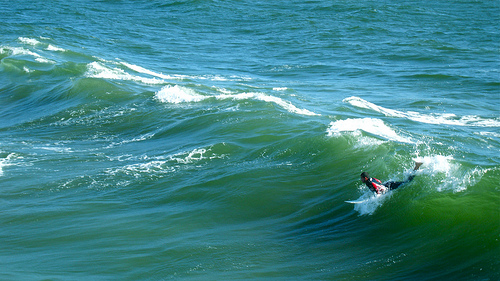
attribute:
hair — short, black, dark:
[360, 171, 371, 179]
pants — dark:
[384, 169, 417, 193]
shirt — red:
[366, 177, 389, 193]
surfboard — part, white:
[342, 178, 419, 206]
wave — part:
[201, 117, 499, 239]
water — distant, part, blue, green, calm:
[2, 1, 499, 36]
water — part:
[1, 207, 498, 281]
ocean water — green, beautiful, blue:
[1, 1, 343, 280]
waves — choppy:
[0, 34, 355, 183]